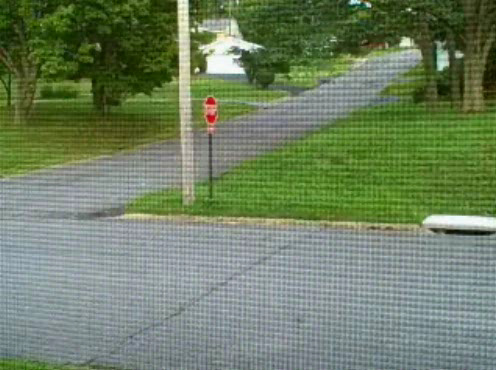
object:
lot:
[179, 71, 276, 109]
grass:
[325, 124, 431, 197]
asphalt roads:
[1, 240, 484, 367]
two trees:
[1, 0, 175, 128]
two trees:
[424, 0, 494, 113]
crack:
[146, 280, 230, 328]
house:
[199, 37, 266, 75]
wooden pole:
[176, 0, 195, 207]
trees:
[457, 0, 495, 113]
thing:
[420, 214, 496, 235]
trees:
[230, 1, 336, 89]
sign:
[202, 96, 218, 135]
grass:
[10, 112, 90, 155]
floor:
[102, 244, 279, 338]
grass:
[288, 68, 315, 81]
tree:
[2, 2, 84, 127]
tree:
[69, 0, 176, 109]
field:
[0, 43, 496, 370]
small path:
[221, 98, 266, 110]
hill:
[341, 49, 412, 98]